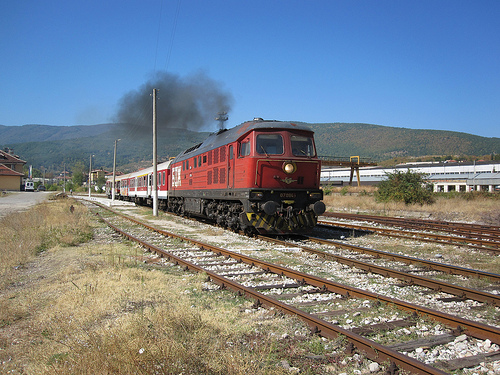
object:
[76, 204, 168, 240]
railroad track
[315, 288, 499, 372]
railroad tracks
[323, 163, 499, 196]
warehouses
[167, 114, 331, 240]
red car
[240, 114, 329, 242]
front train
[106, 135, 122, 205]
light poles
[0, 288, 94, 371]
dead grass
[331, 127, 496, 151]
hills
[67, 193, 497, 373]
tracks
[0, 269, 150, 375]
grassy ground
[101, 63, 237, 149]
black smoke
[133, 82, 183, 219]
lamp posts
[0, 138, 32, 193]
building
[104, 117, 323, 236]
moving train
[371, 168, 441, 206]
bush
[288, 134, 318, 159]
window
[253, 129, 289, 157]
window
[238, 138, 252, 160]
window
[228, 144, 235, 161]
window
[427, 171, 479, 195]
buildings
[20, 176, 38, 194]
van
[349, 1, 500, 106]
sky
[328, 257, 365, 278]
stones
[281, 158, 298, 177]
headlight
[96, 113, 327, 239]
train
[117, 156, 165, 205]
cars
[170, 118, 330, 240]
engine